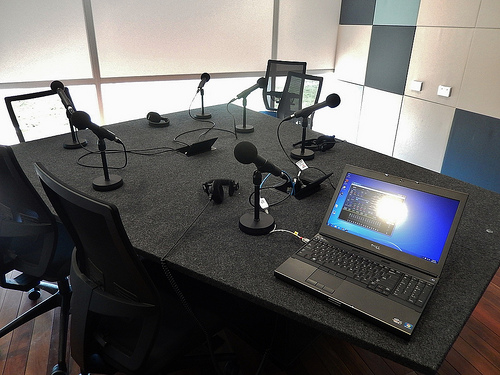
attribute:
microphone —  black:
[231, 135, 293, 186]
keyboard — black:
[293, 235, 435, 313]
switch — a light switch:
[407, 70, 474, 121]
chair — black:
[27, 156, 205, 370]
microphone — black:
[185, 68, 215, 121]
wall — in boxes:
[397, 47, 499, 133]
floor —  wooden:
[459, 324, 496, 364]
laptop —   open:
[273, 163, 468, 338]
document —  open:
[337, 180, 409, 237]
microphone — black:
[33, 66, 97, 152]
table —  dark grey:
[8, 90, 492, 372]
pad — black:
[305, 264, 344, 293]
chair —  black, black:
[30, 161, 216, 373]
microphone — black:
[230, 140, 297, 233]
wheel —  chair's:
[26, 290, 47, 304]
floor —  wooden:
[2, 282, 68, 373]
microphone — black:
[227, 74, 269, 136]